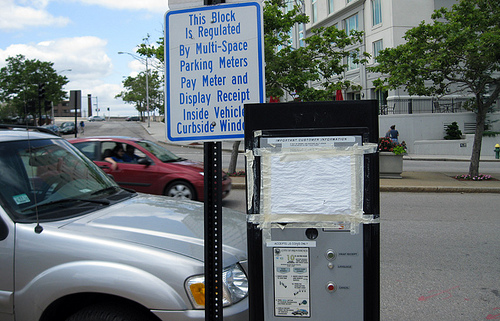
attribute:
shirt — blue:
[99, 140, 150, 160]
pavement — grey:
[53, 116, 496, 317]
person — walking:
[80, 119, 85, 136]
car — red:
[35, 136, 231, 201]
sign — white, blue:
[160, 3, 277, 148]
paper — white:
[232, 133, 367, 240]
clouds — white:
[0, 0, 167, 122]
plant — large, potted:
[377, 137, 407, 154]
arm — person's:
[105, 157, 120, 171]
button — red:
[326, 282, 336, 292]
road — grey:
[401, 193, 488, 318]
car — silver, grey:
[1, 127, 247, 317]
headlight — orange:
[194, 287, 208, 306]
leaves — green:
[1, 53, 70, 113]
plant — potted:
[382, 140, 407, 170]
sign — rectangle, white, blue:
[165, 3, 267, 143]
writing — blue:
[178, 13, 257, 135]